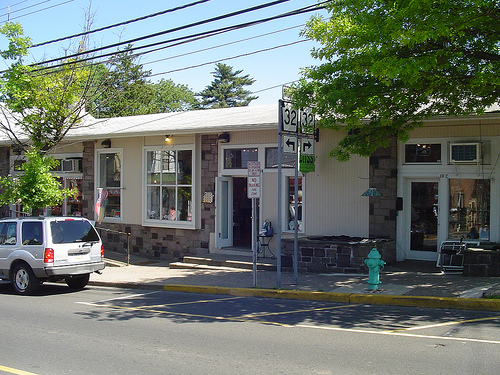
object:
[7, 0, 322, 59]
blue sky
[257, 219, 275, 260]
table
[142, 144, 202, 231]
window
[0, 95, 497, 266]
building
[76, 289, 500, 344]
lines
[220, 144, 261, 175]
window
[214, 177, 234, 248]
door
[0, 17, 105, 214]
tree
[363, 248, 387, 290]
hydrant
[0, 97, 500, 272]
long house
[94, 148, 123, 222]
window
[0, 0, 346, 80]
power lines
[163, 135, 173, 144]
light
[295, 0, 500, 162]
tree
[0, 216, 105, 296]
car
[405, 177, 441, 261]
door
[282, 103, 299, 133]
sign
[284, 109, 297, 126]
32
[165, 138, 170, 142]
light bulb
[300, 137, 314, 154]
sign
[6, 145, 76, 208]
leaves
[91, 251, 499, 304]
sidewalk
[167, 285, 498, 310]
sidewalk edge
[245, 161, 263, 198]
sign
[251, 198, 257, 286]
pole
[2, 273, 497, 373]
roadside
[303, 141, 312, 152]
arrow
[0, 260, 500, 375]
road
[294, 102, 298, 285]
pole